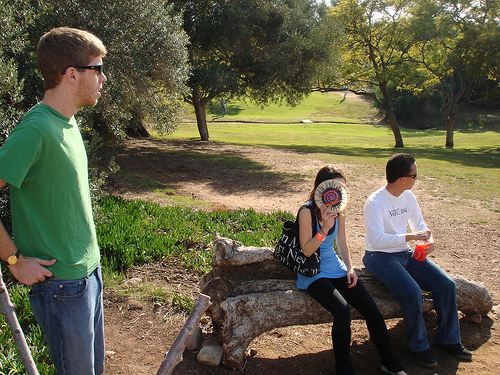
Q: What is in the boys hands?
A: His drink.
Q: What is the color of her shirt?
A: Blue.